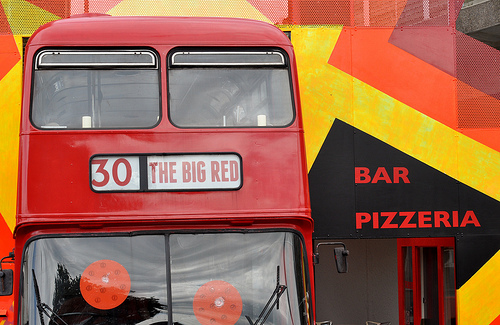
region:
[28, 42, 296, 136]
two bus windows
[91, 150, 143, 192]
30 printed in red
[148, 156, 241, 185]
Text reading The Big Red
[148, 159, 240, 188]
red print text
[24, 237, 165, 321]
window with a red circle on it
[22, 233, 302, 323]
bus window with two red circles on it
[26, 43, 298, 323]
bus windows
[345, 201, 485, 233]
red print reading Pizzeria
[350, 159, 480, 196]
red print reading BAR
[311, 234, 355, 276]
bus mirror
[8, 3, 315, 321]
the bus is red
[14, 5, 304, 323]
the bus has 2 levels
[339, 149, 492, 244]
the sign says bar pizzeria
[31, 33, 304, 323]
the bus has 4 windows on front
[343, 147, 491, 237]
the letters are red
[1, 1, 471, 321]
the wall is yellow orange and red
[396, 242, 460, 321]
the doors are red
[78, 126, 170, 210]
the bus number is 30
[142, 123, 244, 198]
the bus says the big red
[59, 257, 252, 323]
2 red circles are on the windshield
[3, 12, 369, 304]
A double decker red bus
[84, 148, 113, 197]
The red number "3"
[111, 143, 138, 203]
The red number "0"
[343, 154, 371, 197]
A red letter "B"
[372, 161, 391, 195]
A red letter "A"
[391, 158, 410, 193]
A red letter "R"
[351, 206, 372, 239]
A red letter "P"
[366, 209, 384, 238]
A red letter "I"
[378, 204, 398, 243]
A red letter "Z"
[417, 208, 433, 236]
A red letter "E"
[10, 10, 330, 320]
A red bus.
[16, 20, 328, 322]
A double decker bus.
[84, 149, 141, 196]
The number 30 in red.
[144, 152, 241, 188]
The words THE BIG RED.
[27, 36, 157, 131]
Right window on top of bus.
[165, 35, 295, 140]
Left window on top of bus.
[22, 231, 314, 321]
Windshield on bottom of bus.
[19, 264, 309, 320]
Windsheild wipers on bottom of bus.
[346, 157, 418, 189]
The word BAR in red letters.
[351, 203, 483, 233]
The word PIZZERIA in red letters.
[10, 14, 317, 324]
a red double decker bus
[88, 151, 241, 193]
white sign on the bus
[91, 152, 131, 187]
red numbers on the bus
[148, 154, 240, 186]
red letters on the bus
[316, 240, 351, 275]
side mirror on the bus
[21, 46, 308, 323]
front windows of the bus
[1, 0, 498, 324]
a colorful building behind the bus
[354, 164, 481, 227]
red words on the building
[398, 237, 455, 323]
red door of the building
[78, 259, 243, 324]
red circles on bus window